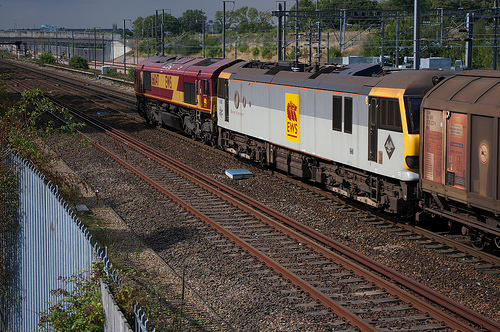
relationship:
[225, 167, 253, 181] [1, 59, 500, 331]
box in middle of tracks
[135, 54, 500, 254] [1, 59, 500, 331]
train on tracks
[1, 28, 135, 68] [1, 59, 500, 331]
bridge behind tracks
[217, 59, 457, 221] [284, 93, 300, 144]
train car has sign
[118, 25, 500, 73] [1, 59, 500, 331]
cliff next to tracks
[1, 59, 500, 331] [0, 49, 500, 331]
tracks on ground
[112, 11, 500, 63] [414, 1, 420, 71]
wires on pole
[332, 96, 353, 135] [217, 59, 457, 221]
windows on train car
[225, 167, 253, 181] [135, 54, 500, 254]
box near train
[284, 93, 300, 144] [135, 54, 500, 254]
sign on train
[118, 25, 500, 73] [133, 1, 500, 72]
cliff covered in trees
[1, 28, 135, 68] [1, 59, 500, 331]
bridge crossing tracks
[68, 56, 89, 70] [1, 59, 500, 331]
bush growing near tracks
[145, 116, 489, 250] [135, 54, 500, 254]
wheels supporting train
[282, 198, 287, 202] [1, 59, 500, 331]
rock near tracks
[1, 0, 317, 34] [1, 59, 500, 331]
sky above tracks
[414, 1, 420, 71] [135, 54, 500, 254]
pole behind train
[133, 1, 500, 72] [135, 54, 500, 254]
trees behind train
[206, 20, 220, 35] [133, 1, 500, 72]
building behind trees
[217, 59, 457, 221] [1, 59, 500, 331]
train car on tracks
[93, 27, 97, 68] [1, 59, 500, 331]
post on tracks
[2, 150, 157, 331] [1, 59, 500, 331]
fence next to tracks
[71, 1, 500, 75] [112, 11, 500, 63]
poles have wires